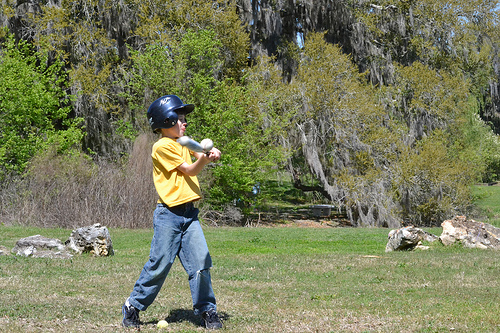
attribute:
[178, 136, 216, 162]
bat — metal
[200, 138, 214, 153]
ball — white, mid air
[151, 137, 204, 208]
shirt — yellow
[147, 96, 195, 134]
helmet — black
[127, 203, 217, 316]
jeans — blue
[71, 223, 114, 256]
rock — grey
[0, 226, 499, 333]
ground — sparse with grass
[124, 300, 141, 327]
shoe — black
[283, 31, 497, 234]
tree — dead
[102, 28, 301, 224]
tree — background